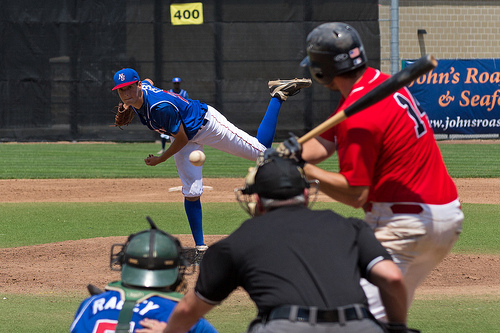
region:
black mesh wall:
[5, 5, 376, 135]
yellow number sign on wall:
[159, 2, 210, 25]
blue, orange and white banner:
[400, 51, 498, 138]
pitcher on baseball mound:
[102, 62, 307, 258]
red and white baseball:
[189, 147, 211, 167]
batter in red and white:
[264, 15, 468, 331]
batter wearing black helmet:
[273, 17, 475, 323]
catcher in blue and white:
[65, 210, 228, 331]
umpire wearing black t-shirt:
[165, 146, 432, 329]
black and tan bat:
[267, 45, 449, 150]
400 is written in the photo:
[168, 0, 215, 32]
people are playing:
[93, 52, 477, 331]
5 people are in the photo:
[71, 42, 499, 329]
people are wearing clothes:
[63, 45, 463, 330]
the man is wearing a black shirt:
[223, 207, 405, 332]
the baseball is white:
[185, 147, 215, 173]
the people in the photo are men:
[52, 43, 459, 330]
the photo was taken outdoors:
[3, 4, 498, 328]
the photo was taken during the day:
[3, 8, 498, 331]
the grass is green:
[5, 146, 145, 175]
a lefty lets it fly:
[90, 55, 315, 264]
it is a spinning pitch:
[82, 56, 314, 264]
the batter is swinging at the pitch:
[52, 2, 468, 331]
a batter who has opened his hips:
[245, 15, 466, 325]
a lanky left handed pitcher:
[107, 55, 326, 262]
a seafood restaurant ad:
[398, 57, 498, 142]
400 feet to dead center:
[171, 0, 220, 314]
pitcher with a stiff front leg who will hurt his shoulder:
[100, 41, 318, 264]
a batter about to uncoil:
[260, 18, 467, 330]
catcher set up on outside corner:
[60, 23, 475, 327]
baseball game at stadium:
[92, 8, 472, 331]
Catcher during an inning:
[59, 209, 226, 331]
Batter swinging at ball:
[279, 53, 483, 248]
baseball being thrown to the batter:
[170, 137, 222, 184]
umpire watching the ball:
[216, 152, 419, 328]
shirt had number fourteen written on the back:
[389, 97, 439, 157]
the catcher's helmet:
[106, 226, 198, 305]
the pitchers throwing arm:
[138, 122, 215, 184]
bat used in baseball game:
[283, 47, 441, 146]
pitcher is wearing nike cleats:
[249, 65, 317, 118]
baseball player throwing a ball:
[101, 68, 241, 202]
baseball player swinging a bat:
[255, 27, 450, 164]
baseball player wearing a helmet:
[296, 22, 373, 73]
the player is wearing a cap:
[108, 68, 150, 88]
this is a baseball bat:
[300, 56, 442, 132]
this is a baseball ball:
[185, 151, 211, 168]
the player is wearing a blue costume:
[141, 88, 207, 134]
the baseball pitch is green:
[11, 201, 109, 245]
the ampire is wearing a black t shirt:
[204, 208, 380, 315]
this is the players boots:
[266, 78, 316, 99]